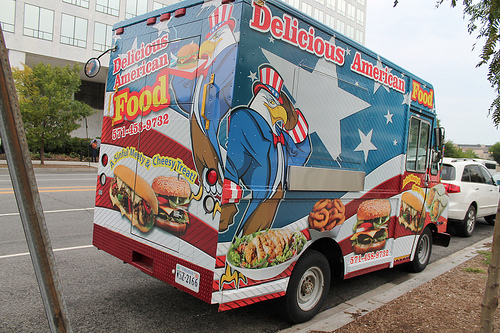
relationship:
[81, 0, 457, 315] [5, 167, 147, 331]
truck on road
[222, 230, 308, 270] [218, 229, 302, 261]
green salad with grilled chicken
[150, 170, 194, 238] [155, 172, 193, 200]
burger on a sesame roll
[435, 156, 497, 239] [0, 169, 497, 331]
car in roadway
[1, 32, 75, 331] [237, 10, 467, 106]
pole for a sign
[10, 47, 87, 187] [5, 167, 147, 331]
tree planted across road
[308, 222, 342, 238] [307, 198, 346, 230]
container overflowing with onion rings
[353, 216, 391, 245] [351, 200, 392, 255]
cheeseburger on a bun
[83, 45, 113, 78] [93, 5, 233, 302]
convex mirror attached to back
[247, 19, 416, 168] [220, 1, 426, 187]
stars on food truck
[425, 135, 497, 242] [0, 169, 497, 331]
car on roadway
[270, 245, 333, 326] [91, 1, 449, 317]
wheel on food truck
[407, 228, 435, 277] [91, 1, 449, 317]
wheel on food truck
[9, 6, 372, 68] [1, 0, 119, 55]
building with windows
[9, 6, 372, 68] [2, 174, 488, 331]
building across street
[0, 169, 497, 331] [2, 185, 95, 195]
roadway with stripes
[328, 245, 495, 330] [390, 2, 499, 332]
dirt under tree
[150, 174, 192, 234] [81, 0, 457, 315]
burger on truck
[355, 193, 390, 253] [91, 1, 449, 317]
hamburger on food truck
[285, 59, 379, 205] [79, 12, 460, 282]
window of truck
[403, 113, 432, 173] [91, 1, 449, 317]
window of food truck